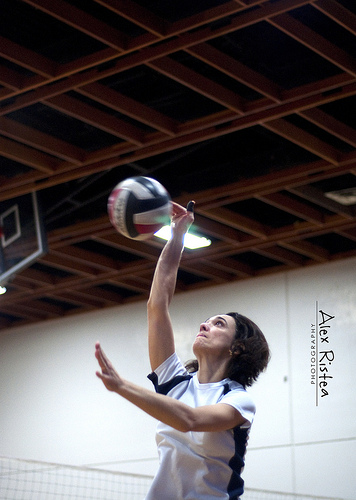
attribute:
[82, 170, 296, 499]
person — bandaged, brunette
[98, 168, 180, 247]
ball — red, black, striped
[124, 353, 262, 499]
uniform — white, striped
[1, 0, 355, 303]
ceiling — wooden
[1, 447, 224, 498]
net — white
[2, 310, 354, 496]
wall — white